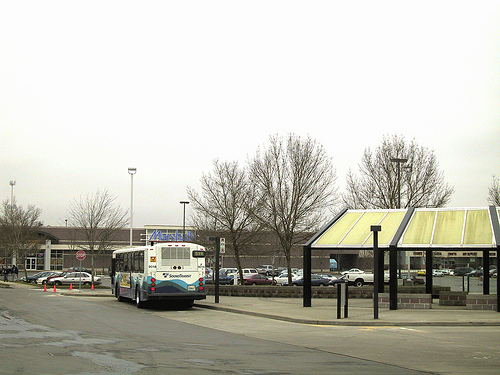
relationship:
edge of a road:
[193, 302, 499, 327] [0, 293, 499, 373]